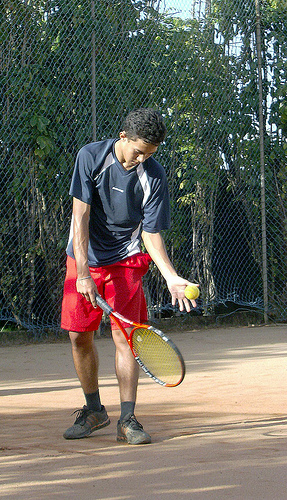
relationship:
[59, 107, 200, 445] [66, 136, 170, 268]
boy wearing t-shirt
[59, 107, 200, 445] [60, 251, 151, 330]
boy wearing shorts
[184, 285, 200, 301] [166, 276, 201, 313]
ball in hand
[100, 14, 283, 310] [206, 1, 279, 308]
leaves on tree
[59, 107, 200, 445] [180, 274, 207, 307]
boy holding ball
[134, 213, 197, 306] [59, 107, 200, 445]
arm of boy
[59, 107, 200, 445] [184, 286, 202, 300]
boy with a tennis ball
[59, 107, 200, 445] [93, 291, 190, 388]
boy holding racket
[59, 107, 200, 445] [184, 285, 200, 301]
boy holding ball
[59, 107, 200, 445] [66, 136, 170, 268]
boy in t-shirt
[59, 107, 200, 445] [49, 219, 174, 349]
boy wearing shorts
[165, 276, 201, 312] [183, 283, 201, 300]
hand throwing ball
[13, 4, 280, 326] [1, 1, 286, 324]
tree behind fence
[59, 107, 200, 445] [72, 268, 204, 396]
boy holding racket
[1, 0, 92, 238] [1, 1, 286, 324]
trees behind fence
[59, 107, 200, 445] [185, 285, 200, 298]
boy looking toward tennis ball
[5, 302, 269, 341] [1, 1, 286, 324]
opening in fence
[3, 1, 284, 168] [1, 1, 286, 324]
sky behind fence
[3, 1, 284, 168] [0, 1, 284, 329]
sky behind trees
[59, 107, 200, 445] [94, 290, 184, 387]
boy holding tennis racket